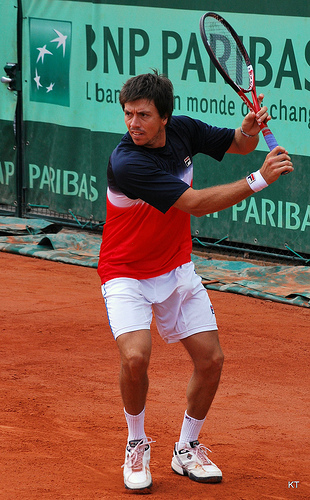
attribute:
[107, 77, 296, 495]
man — playing, bending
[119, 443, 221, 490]
shoes — white, tied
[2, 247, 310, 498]
court — orange, clay, brown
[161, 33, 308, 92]
word — pariba, green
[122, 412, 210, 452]
socks — white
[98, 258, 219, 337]
shorts — white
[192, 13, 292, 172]
racquet — black, red, red black, blue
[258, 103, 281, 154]
handle — blue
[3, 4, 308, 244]
sign — green, designed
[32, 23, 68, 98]
stars — white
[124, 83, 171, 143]
face — concentrating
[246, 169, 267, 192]
band — white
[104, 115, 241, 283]
shirt — red white, blue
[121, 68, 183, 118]
hair — black, neat